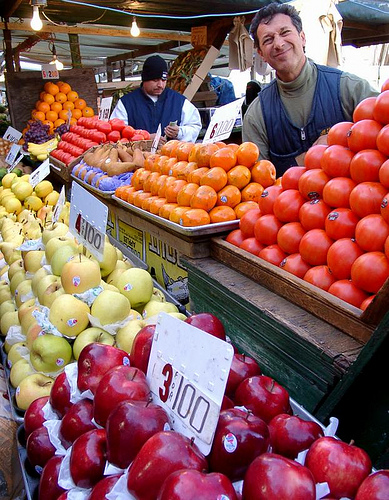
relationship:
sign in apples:
[143, 311, 235, 459] [21, 310, 387, 498]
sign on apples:
[67, 178, 108, 263] [0, 217, 187, 410]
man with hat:
[110, 53, 202, 148] [139, 52, 170, 81]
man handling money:
[110, 53, 202, 148] [165, 117, 180, 138]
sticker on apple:
[121, 355, 131, 367] [77, 343, 134, 396]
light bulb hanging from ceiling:
[126, 14, 141, 39] [1, 0, 387, 38]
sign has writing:
[143, 311, 235, 459] [156, 363, 209, 436]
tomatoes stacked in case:
[226, 77, 388, 311] [210, 232, 388, 342]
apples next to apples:
[0, 217, 187, 410] [21, 310, 387, 498]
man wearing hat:
[110, 53, 202, 148] [139, 52, 170, 81]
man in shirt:
[239, 0, 377, 177] [241, 56, 373, 167]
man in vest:
[239, 0, 377, 177] [256, 64, 345, 178]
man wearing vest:
[110, 53, 202, 148] [117, 88, 188, 143]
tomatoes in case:
[226, 77, 388, 311] [210, 232, 388, 342]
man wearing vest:
[239, 0, 377, 177] [256, 64, 345, 178]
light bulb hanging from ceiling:
[28, 6, 44, 33] [1, 0, 387, 38]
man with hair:
[239, 0, 377, 177] [246, 1, 304, 50]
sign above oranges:
[38, 60, 63, 79] [17, 77, 96, 145]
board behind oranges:
[5, 67, 102, 133] [17, 77, 96, 145]